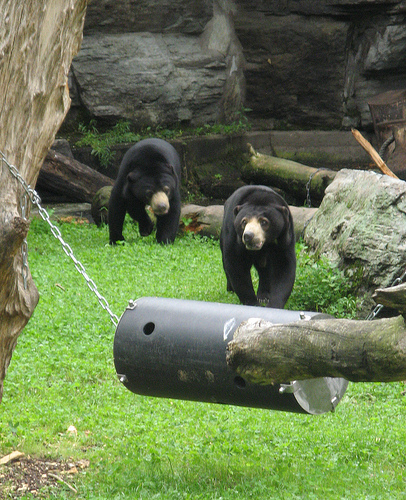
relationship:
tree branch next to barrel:
[225, 314, 404, 385] [113, 295, 349, 415]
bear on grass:
[99, 132, 187, 247] [7, 207, 397, 490]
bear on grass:
[219, 176, 301, 308] [7, 207, 397, 490]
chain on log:
[294, 156, 331, 212] [236, 140, 345, 219]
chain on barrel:
[3, 150, 119, 336] [113, 295, 349, 415]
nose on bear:
[240, 227, 257, 243] [211, 174, 300, 320]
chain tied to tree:
[3, 150, 119, 336] [0, 0, 88, 399]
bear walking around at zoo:
[219, 176, 301, 308] [7, 4, 401, 496]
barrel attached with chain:
[113, 295, 349, 415] [0, 151, 119, 328]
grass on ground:
[127, 413, 393, 491] [1, 217, 404, 497]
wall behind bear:
[91, 0, 403, 120] [107, 136, 185, 247]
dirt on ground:
[3, 410, 118, 498] [1, 217, 404, 497]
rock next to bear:
[298, 164, 404, 321] [219, 176, 301, 308]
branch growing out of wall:
[350, 126, 397, 178] [296, 95, 384, 136]